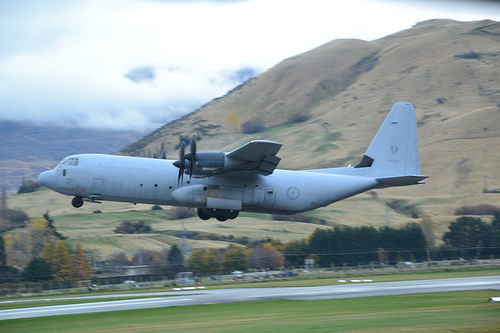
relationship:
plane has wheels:
[37, 100, 428, 242] [65, 189, 250, 226]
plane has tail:
[37, 100, 428, 242] [365, 93, 429, 197]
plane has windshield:
[37, 100, 428, 242] [58, 154, 80, 168]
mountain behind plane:
[257, 20, 499, 85] [37, 100, 428, 242]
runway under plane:
[12, 275, 498, 321] [37, 100, 428, 242]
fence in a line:
[298, 256, 491, 278] [304, 263, 477, 277]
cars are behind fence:
[239, 270, 303, 284] [298, 256, 491, 278]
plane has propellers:
[37, 100, 428, 242] [171, 139, 203, 186]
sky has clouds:
[9, 84, 54, 118] [63, 16, 230, 85]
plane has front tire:
[37, 100, 428, 242] [71, 193, 87, 209]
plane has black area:
[37, 100, 428, 242] [350, 152, 377, 174]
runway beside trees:
[12, 275, 498, 321] [301, 226, 427, 264]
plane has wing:
[37, 100, 428, 242] [219, 138, 287, 181]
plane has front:
[37, 100, 428, 242] [34, 149, 118, 218]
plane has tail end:
[37, 100, 428, 242] [365, 93, 429, 197]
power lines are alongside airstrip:
[16, 242, 495, 289] [12, 275, 498, 321]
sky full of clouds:
[9, 84, 54, 118] [63, 16, 230, 85]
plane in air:
[37, 100, 428, 242] [38, 20, 267, 116]